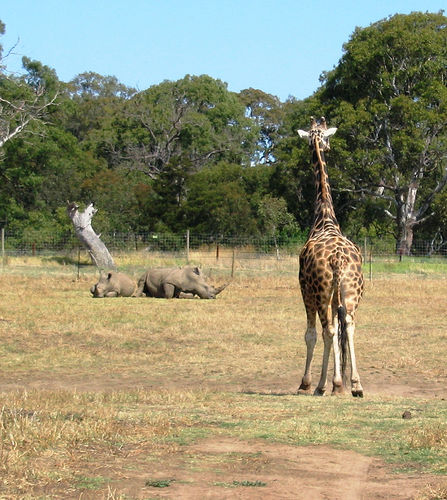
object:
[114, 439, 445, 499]
bald spot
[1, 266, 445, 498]
grass area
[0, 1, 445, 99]
sky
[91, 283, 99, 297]
rhino horn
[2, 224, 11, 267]
post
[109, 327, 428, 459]
grass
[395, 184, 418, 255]
trunk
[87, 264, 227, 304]
rhino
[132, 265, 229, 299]
hippo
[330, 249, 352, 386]
tail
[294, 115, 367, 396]
animal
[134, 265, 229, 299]
animal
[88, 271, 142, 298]
animal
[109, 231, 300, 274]
enclosure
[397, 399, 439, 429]
stone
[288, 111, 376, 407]
giraffe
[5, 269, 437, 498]
field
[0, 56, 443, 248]
trees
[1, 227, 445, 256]
fence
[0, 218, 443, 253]
bush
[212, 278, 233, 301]
horn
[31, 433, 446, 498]
dirt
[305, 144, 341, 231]
neck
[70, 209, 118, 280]
tree trunk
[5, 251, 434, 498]
ground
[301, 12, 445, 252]
tree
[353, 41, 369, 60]
leaves